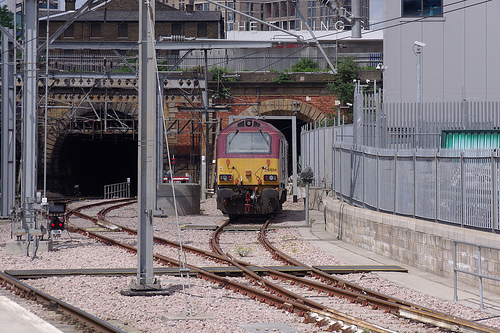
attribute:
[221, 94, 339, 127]
wall — brick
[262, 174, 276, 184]
light — unlit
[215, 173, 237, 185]
light — unlit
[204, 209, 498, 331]
tracks — split up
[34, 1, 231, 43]
bulding — large, brick, dark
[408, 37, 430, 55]
video camera — small, white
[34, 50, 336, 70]
railing — silver, metal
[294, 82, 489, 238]
fencing — silver, metal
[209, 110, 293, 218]
train — red, yellow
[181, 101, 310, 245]
train — red, yellow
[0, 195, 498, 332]
gravel — brown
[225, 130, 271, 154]
windshield — dusty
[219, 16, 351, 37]
letters — silver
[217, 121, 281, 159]
windhsield — long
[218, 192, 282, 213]
plate — black, metal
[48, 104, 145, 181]
archway — stone